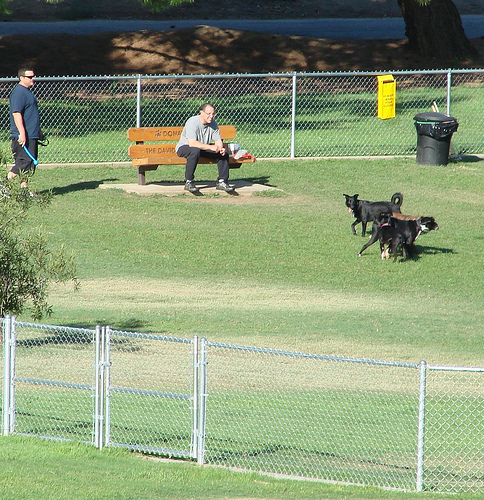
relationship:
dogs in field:
[340, 188, 432, 265] [0, 130, 461, 457]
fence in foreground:
[15, 341, 469, 489] [5, 227, 473, 499]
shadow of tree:
[58, 69, 378, 140] [390, 3, 466, 75]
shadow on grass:
[58, 69, 378, 140] [28, 96, 460, 379]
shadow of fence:
[20, 401, 483, 492] [15, 341, 469, 489]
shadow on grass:
[20, 401, 483, 492] [28, 96, 460, 379]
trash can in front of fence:
[416, 110, 449, 187] [10, 62, 474, 150]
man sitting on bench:
[180, 93, 223, 180] [123, 122, 232, 169]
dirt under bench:
[115, 178, 271, 196] [123, 122, 232, 169]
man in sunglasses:
[16, 62, 46, 186] [23, 73, 39, 83]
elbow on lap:
[183, 137, 195, 155] [172, 141, 211, 156]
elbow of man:
[183, 137, 195, 155] [180, 93, 223, 180]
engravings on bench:
[154, 129, 182, 137] [123, 122, 232, 169]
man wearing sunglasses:
[16, 62, 46, 186] [23, 73, 39, 83]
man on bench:
[180, 93, 223, 180] [123, 122, 232, 169]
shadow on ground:
[58, 69, 378, 140] [12, 146, 483, 482]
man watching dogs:
[5, 67, 50, 198] [340, 188, 432, 265]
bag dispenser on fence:
[377, 74, 396, 120] [10, 62, 474, 150]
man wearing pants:
[180, 93, 223, 180] [173, 157, 217, 180]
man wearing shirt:
[180, 93, 223, 180] [187, 132, 218, 155]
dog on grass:
[381, 227, 428, 261] [28, 96, 460, 379]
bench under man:
[123, 122, 232, 169] [180, 93, 223, 180]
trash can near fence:
[416, 110, 449, 187] [0, 317, 483, 490]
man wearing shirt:
[16, 62, 46, 186] [13, 92, 49, 135]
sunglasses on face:
[23, 73, 39, 83] [26, 71, 39, 89]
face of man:
[26, 71, 39, 89] [16, 62, 46, 186]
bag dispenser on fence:
[377, 74, 396, 120] [0, 66, 483, 166]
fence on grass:
[15, 341, 469, 489] [28, 96, 460, 379]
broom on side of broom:
[454, 144, 473, 168] [431, 100, 465, 162]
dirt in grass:
[115, 178, 271, 196] [28, 96, 460, 379]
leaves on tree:
[24, 212, 37, 232] [0, 170, 69, 277]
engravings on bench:
[148, 128, 176, 137] [123, 122, 232, 169]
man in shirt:
[16, 62, 46, 186] [13, 92, 49, 135]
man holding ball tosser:
[16, 62, 46, 186] [18, 146, 39, 165]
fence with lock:
[0, 317, 483, 490] [98, 358, 115, 371]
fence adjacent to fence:
[15, 341, 469, 489] [0, 317, 483, 490]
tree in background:
[390, 3, 466, 75] [28, 5, 467, 105]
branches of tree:
[2, 287, 14, 306] [0, 170, 69, 277]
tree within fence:
[0, 170, 69, 277] [15, 341, 469, 489]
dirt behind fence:
[55, 23, 380, 64] [10, 62, 474, 150]